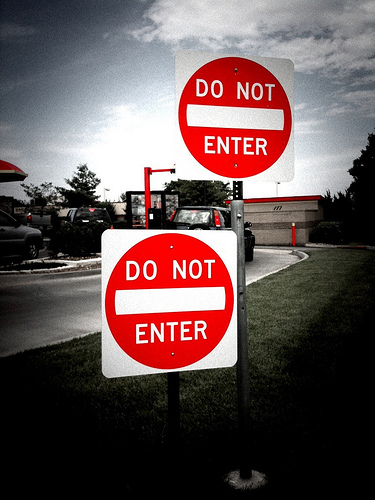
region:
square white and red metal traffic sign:
[169, 48, 296, 183]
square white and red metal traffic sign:
[95, 224, 242, 380]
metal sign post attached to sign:
[165, 361, 182, 498]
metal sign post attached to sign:
[218, 175, 269, 498]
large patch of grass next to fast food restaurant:
[2, 246, 373, 498]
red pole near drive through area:
[289, 219, 299, 247]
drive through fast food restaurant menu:
[123, 188, 183, 239]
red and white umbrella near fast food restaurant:
[0, 157, 30, 185]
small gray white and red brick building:
[211, 194, 329, 249]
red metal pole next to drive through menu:
[139, 157, 179, 247]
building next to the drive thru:
[257, 191, 311, 246]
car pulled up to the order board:
[173, 195, 262, 274]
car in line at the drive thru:
[47, 205, 107, 246]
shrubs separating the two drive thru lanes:
[52, 218, 106, 256]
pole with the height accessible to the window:
[140, 164, 180, 213]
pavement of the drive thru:
[14, 284, 94, 325]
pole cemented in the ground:
[229, 459, 267, 492]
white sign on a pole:
[161, 33, 313, 193]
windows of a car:
[169, 204, 217, 229]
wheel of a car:
[30, 235, 39, 257]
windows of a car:
[72, 206, 112, 223]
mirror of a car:
[239, 218, 252, 229]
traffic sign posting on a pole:
[93, 211, 252, 380]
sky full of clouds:
[122, 14, 327, 47]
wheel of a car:
[246, 234, 254, 261]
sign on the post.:
[93, 222, 243, 383]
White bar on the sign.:
[108, 281, 224, 315]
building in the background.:
[220, 189, 320, 244]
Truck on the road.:
[142, 195, 250, 265]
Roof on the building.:
[0, 150, 25, 185]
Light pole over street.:
[138, 159, 177, 227]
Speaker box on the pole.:
[146, 203, 163, 225]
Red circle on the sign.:
[170, 50, 296, 182]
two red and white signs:
[61, 35, 326, 388]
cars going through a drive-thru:
[4, 161, 118, 278]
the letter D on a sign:
[192, 77, 208, 97]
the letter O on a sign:
[209, 77, 225, 99]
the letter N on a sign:
[235, 78, 250, 102]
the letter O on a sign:
[250, 82, 263, 99]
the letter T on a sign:
[264, 81, 276, 101]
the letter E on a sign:
[202, 134, 215, 154]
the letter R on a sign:
[255, 136, 269, 157]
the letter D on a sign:
[122, 257, 141, 282]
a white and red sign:
[99, 228, 239, 374]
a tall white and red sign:
[174, 48, 294, 185]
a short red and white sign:
[100, 230, 240, 495]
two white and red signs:
[111, 52, 292, 467]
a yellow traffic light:
[141, 158, 179, 237]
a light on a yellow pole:
[138, 161, 177, 230]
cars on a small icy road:
[0, 198, 250, 274]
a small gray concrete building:
[220, 197, 323, 245]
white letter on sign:
[193, 77, 208, 98]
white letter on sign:
[125, 258, 138, 282]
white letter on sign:
[141, 257, 158, 279]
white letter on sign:
[170, 255, 190, 280]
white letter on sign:
[187, 258, 203, 280]